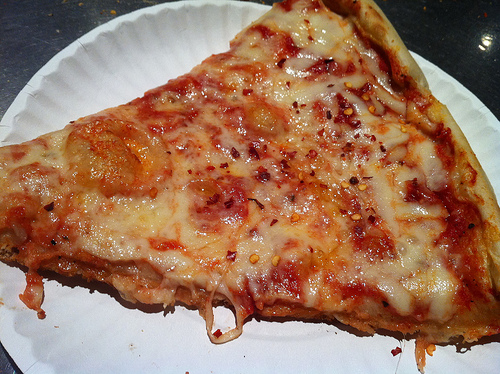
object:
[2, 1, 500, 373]
plate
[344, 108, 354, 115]
spices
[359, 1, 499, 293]
crust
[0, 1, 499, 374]
cheese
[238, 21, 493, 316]
red sauce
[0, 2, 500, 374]
surface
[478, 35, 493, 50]
light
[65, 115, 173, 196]
bubble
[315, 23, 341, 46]
spot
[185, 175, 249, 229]
pepperoni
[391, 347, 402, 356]
crumb